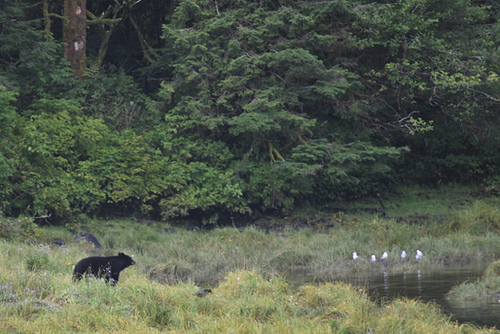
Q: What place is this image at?
A: It is at the forest.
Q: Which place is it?
A: It is a forest.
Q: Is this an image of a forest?
A: Yes, it is showing a forest.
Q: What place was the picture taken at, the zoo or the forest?
A: It was taken at the forest.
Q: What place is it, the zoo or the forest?
A: It is the forest.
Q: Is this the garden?
A: No, it is the forest.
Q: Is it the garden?
A: No, it is the forest.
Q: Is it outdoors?
A: Yes, it is outdoors.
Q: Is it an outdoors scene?
A: Yes, it is outdoors.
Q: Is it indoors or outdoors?
A: It is outdoors.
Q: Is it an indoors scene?
A: No, it is outdoors.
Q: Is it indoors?
A: No, it is outdoors.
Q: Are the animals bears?
A: No, there are both birds and bears.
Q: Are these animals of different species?
A: Yes, they are birds and bears.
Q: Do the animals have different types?
A: Yes, they are birds and bears.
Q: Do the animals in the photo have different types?
A: Yes, they are birds and bears.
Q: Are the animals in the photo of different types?
A: Yes, they are birds and bears.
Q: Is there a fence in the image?
A: No, there are no fences.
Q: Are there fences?
A: No, there are no fences.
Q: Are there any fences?
A: No, there are no fences.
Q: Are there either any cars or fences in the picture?
A: No, there are no fences or cars.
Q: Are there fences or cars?
A: No, there are no fences or cars.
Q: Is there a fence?
A: No, there are no fences.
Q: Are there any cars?
A: No, there are no cars.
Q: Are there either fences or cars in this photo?
A: No, there are no cars or fences.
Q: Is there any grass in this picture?
A: Yes, there is grass.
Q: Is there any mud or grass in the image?
A: Yes, there is grass.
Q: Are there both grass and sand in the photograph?
A: No, there is grass but no sand.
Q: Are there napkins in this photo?
A: No, there are no napkins.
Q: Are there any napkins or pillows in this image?
A: No, there are no napkins or pillows.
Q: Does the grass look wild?
A: Yes, the grass is wild.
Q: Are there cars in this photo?
A: No, there are no cars.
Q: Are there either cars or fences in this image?
A: No, there are no cars or fences.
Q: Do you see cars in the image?
A: No, there are no cars.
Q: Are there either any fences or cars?
A: No, there are no cars or fences.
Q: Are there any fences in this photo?
A: No, there are no fences.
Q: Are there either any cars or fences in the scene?
A: No, there are no fences or cars.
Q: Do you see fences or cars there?
A: No, there are no fences or cars.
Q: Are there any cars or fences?
A: No, there are no fences or cars.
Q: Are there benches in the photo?
A: No, there are no benches.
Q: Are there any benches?
A: No, there are no benches.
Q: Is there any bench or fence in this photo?
A: No, there are no benches or fences.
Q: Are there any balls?
A: No, there are no balls.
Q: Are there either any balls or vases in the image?
A: No, there are no balls or vases.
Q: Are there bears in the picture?
A: Yes, there is a bear.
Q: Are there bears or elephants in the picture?
A: Yes, there is a bear.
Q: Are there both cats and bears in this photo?
A: No, there is a bear but no cats.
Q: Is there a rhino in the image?
A: No, there are no rhinos.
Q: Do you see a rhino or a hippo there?
A: No, there are no rhinos or hippoes.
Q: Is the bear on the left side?
A: Yes, the bear is on the left of the image.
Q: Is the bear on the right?
A: No, the bear is on the left of the image.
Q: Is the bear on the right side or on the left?
A: The bear is on the left of the image.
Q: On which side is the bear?
A: The bear is on the left of the image.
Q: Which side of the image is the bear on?
A: The bear is on the left of the image.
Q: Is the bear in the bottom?
A: Yes, the bear is in the bottom of the image.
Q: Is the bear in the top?
A: No, the bear is in the bottom of the image.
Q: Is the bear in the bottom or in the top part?
A: The bear is in the bottom of the image.